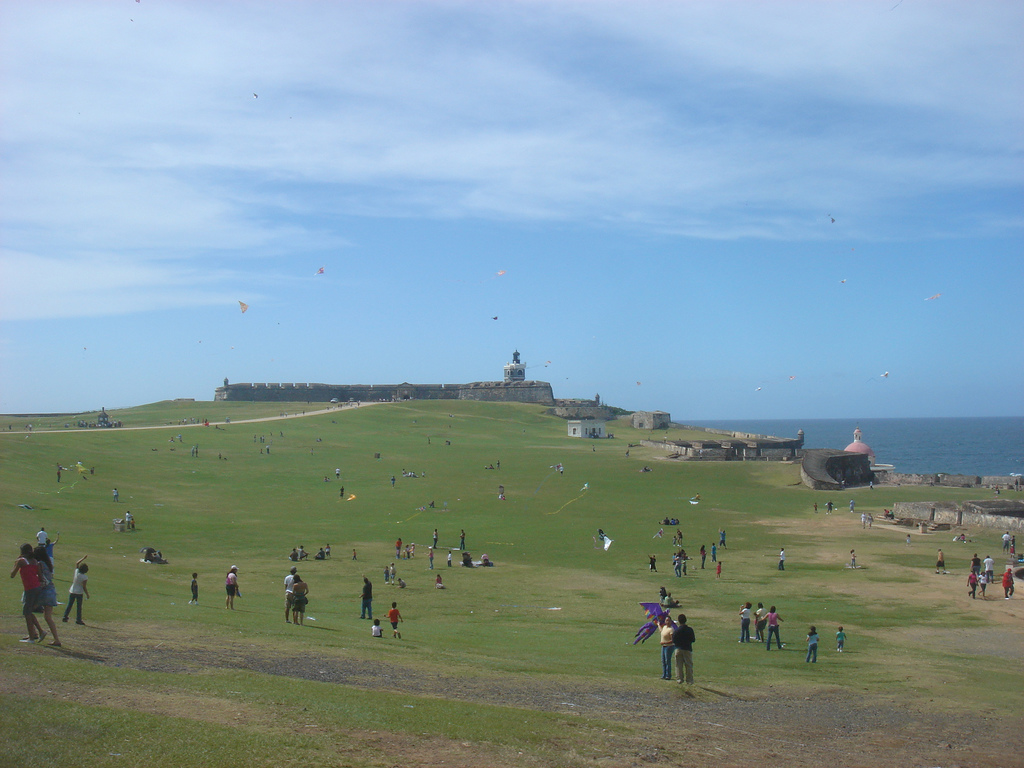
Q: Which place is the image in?
A: It is at the field.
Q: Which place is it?
A: It is a field.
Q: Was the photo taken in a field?
A: Yes, it was taken in a field.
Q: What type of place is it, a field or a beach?
A: It is a field.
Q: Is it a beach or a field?
A: It is a field.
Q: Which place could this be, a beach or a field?
A: It is a field.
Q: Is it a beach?
A: No, it is a field.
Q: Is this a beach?
A: No, it is a field.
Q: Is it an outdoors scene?
A: Yes, it is outdoors.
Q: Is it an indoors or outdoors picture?
A: It is outdoors.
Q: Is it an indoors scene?
A: No, it is outdoors.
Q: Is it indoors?
A: No, it is outdoors.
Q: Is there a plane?
A: No, there are no airplanes.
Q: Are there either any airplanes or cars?
A: No, there are no airplanes or cars.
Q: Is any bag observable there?
A: No, there are no bags.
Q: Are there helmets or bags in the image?
A: No, there are no bags or helmets.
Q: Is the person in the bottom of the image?
A: Yes, the person is in the bottom of the image.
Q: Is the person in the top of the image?
A: No, the person is in the bottom of the image.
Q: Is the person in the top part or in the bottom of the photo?
A: The person is in the bottom of the image.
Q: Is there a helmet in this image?
A: No, there are no helmets.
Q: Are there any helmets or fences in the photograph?
A: No, there are no helmets or fences.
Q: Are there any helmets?
A: No, there are no helmets.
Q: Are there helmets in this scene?
A: No, there are no helmets.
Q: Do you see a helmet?
A: No, there are no helmets.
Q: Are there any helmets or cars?
A: No, there are no helmets or cars.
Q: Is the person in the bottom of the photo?
A: Yes, the person is in the bottom of the image.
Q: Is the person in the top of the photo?
A: No, the person is in the bottom of the image.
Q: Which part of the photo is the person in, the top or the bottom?
A: The person is in the bottom of the image.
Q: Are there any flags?
A: No, there are no flags.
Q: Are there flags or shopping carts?
A: No, there are no flags or shopping carts.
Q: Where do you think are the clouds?
A: The clouds are in the sky.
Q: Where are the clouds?
A: The clouds are in the sky.